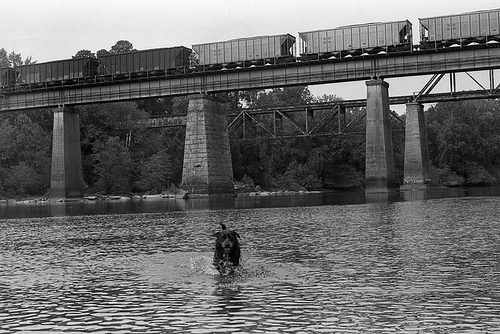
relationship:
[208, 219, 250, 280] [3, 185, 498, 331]
dog moving in water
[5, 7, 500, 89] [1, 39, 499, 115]
train on bridge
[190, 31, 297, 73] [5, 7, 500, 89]
car of train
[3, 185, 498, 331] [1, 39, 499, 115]
water under bridge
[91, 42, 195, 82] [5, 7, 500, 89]
car of train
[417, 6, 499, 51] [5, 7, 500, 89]
car of train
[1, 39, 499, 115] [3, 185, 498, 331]
bridge across water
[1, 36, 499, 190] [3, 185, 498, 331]
vegetation on edge of water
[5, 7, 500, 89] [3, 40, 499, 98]
train on track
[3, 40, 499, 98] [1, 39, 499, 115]
track on bridge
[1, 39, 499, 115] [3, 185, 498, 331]
bridge above water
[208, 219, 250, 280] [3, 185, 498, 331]
dog running in water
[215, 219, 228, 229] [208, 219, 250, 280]
tail of dog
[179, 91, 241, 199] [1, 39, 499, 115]
pillar supports bridge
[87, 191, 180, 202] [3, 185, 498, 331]
rocks on shore of water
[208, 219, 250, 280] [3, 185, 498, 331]
dog in water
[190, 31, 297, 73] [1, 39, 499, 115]
car on bridge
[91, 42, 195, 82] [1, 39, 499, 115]
car on bridge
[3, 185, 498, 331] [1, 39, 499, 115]
water near bridge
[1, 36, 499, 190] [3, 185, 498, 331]
vegetation near water